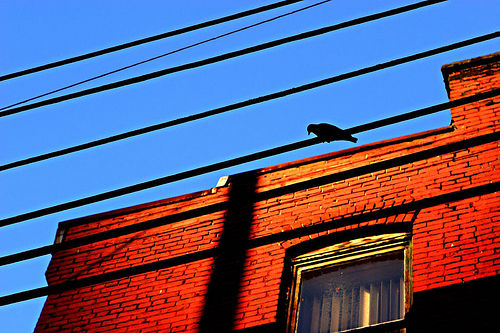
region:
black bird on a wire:
[299, 113, 359, 151]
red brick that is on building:
[64, 227, 106, 255]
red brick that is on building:
[184, 272, 215, 300]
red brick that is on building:
[438, 222, 487, 272]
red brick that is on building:
[292, 172, 347, 203]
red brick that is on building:
[56, 298, 139, 325]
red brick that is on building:
[178, 254, 272, 331]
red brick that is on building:
[435, 61, 498, 128]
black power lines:
[2, 35, 499, 182]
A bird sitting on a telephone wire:
[291, 108, 367, 153]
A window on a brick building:
[265, 216, 463, 331]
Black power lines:
[24, 43, 244, 193]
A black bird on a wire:
[285, 113, 377, 158]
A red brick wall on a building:
[67, 291, 159, 331]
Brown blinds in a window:
[282, 232, 424, 332]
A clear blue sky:
[14, 7, 106, 42]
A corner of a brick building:
[40, 203, 120, 281]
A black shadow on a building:
[177, 192, 262, 329]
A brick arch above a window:
[268, 195, 423, 262]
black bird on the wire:
[301, 119, 358, 146]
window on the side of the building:
[271, 228, 424, 332]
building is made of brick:
[28, 48, 498, 332]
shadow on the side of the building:
[192, 176, 256, 329]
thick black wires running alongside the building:
[0, 8, 498, 316]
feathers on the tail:
[343, 128, 360, 147]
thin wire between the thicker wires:
[3, 0, 336, 120]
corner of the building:
[48, 213, 75, 230]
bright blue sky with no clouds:
[0, 0, 499, 329]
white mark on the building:
[450, 241, 455, 249]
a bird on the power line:
[272, 78, 407, 218]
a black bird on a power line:
[255, 66, 463, 247]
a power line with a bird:
[241, 32, 429, 194]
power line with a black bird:
[182, 28, 497, 267]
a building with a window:
[228, 190, 468, 325]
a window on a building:
[253, 191, 443, 330]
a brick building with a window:
[224, 198, 499, 330]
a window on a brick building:
[194, 181, 490, 331]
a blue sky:
[8, 11, 201, 113]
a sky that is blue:
[17, 16, 379, 252]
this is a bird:
[286, 100, 358, 162]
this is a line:
[23, 24, 491, 141]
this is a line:
[160, 156, 247, 205]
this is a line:
[159, 48, 225, 82]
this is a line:
[251, 34, 320, 66]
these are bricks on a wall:
[123, 232, 192, 287]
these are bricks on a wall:
[459, 152, 497, 227]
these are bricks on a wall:
[87, 221, 139, 280]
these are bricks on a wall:
[284, 174, 333, 219]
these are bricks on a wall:
[376, 172, 443, 219]